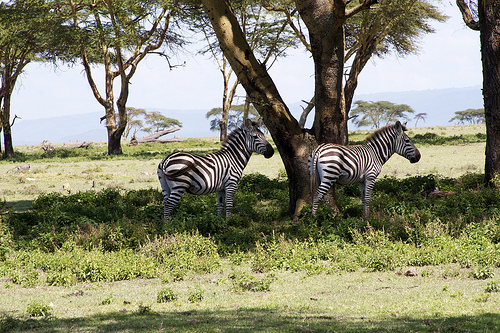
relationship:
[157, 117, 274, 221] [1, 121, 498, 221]
zebra on african plain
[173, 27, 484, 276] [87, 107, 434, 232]
tree shading zebras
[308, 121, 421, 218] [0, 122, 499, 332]
zebra walking on grass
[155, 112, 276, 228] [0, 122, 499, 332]
zebra walking on grass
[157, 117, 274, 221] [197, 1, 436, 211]
zebra near tree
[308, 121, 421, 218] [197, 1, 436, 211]
zebra near tree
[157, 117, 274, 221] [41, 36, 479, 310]
zebra in wild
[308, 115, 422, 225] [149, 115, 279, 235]
zebra following zebra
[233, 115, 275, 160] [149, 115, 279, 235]
head turned on zebra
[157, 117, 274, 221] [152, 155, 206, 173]
zebra wagging its tail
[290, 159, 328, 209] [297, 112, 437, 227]
tail of zebra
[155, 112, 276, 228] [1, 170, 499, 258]
zebra enjoying shade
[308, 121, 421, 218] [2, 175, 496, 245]
zebra enjoying shade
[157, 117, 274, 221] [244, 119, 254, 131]
zebra has ear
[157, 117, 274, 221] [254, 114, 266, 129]
zebra has ear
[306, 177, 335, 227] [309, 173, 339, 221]
part of leg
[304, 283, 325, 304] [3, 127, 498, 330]
part of ground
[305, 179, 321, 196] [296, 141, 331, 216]
part of tail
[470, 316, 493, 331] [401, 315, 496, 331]
part of shade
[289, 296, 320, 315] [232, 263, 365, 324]
part of ground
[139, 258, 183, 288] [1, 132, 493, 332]
part of plain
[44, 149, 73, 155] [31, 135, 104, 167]
part of bush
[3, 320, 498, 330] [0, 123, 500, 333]
edge of grass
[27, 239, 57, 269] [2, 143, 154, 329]
part of plain